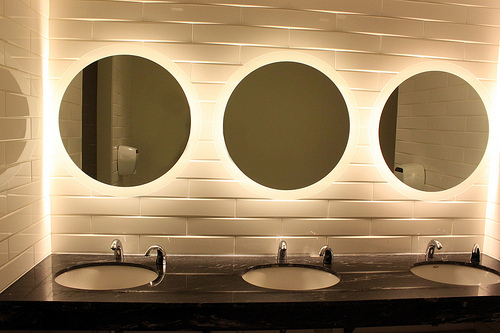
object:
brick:
[288, 30, 385, 56]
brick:
[189, 23, 288, 50]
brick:
[90, 19, 193, 43]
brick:
[382, 36, 464, 59]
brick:
[234, 198, 329, 218]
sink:
[52, 261, 158, 291]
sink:
[411, 259, 500, 285]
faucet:
[111, 241, 125, 259]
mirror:
[377, 69, 488, 191]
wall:
[47, 0, 499, 257]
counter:
[0, 255, 498, 328]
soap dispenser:
[144, 245, 165, 267]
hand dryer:
[116, 144, 138, 176]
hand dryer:
[395, 160, 425, 186]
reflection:
[59, 55, 190, 186]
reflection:
[378, 68, 486, 194]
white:
[112, 135, 146, 180]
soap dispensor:
[112, 130, 156, 187]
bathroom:
[4, 0, 499, 332]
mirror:
[55, 53, 192, 190]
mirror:
[221, 60, 351, 198]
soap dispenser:
[318, 239, 333, 264]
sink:
[249, 262, 343, 292]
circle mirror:
[210, 39, 360, 208]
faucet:
[420, 238, 442, 262]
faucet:
[277, 239, 288, 262]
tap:
[274, 236, 289, 266]